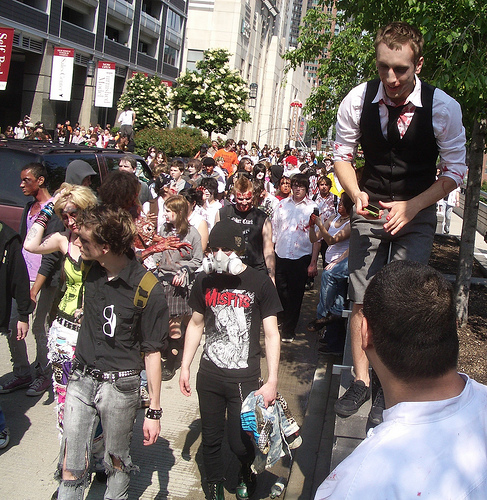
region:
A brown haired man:
[311, 258, 486, 498]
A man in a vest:
[331, 20, 470, 426]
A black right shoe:
[332, 377, 373, 418]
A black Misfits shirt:
[185, 266, 283, 380]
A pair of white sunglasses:
[100, 302, 118, 338]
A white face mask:
[190, 247, 247, 276]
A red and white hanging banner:
[47, 45, 76, 102]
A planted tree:
[279, 0, 486, 326]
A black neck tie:
[382, 100, 410, 142]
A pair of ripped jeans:
[56, 361, 141, 498]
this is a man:
[315, 33, 470, 291]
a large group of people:
[28, 76, 359, 485]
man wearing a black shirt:
[67, 232, 167, 386]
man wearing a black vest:
[339, 40, 451, 229]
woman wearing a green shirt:
[53, 237, 93, 323]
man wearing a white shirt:
[320, 82, 484, 207]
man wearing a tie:
[364, 79, 413, 159]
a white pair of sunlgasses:
[99, 299, 137, 363]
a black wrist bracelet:
[133, 395, 169, 427]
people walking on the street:
[6, 141, 308, 497]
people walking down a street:
[21, 113, 398, 412]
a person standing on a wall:
[341, 38, 454, 336]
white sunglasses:
[101, 302, 119, 337]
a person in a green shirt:
[39, 188, 91, 322]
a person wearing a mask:
[184, 218, 287, 446]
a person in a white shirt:
[282, 179, 317, 285]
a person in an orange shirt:
[211, 135, 235, 162]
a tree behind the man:
[453, 126, 485, 338]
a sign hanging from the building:
[51, 44, 72, 99]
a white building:
[190, 3, 297, 140]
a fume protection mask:
[197, 246, 246, 280]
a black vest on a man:
[354, 61, 449, 215]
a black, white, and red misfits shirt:
[186, 256, 285, 377]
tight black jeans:
[188, 352, 270, 497]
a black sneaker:
[331, 368, 371, 418]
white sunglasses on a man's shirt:
[99, 301, 124, 340]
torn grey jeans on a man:
[58, 340, 142, 497]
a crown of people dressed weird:
[10, 102, 350, 470]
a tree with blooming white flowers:
[172, 40, 241, 137]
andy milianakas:
[284, 164, 314, 210]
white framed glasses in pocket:
[101, 300, 120, 344]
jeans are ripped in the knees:
[56, 460, 92, 489]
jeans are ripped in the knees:
[106, 436, 136, 481]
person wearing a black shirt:
[73, 269, 167, 375]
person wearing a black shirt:
[190, 275, 275, 363]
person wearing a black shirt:
[245, 210, 263, 270]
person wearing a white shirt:
[360, 390, 477, 497]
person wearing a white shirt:
[278, 193, 304, 253]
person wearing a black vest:
[360, 85, 425, 194]